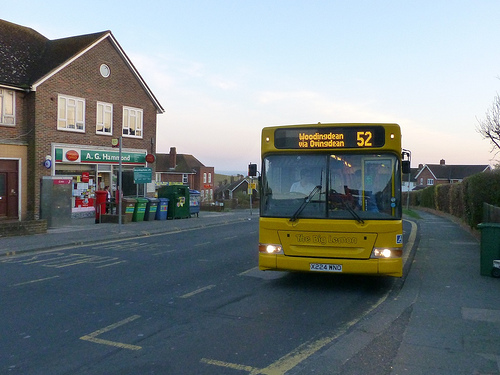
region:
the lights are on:
[255, 245, 424, 266]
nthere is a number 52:
[286, 128, 374, 150]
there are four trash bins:
[119, 199, 174, 218]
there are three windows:
[52, 96, 151, 137]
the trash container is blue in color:
[161, 180, 193, 216]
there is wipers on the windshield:
[280, 190, 360, 225]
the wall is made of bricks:
[67, 87, 150, 101]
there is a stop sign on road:
[37, 245, 116, 288]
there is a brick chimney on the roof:
[165, 142, 181, 170]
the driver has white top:
[283, 175, 324, 203]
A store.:
[31, 35, 169, 243]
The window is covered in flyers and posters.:
[55, 160, 102, 210]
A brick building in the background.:
[152, 145, 212, 211]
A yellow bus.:
[250, 110, 415, 285]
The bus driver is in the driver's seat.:
[276, 165, 321, 210]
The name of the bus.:
[280, 230, 375, 251]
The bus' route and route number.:
[280, 125, 380, 155]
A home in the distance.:
[410, 156, 490, 201]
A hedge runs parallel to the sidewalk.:
[415, 156, 495, 241]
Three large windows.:
[52, 86, 148, 138]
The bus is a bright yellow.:
[240, 126, 446, 312]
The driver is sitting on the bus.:
[283, 167, 320, 209]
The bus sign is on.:
[290, 124, 393, 148]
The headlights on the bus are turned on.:
[264, 231, 445, 261]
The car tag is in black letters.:
[308, 257, 347, 277]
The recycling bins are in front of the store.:
[116, 194, 181, 225]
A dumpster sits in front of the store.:
[160, 180, 206, 227]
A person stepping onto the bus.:
[346, 168, 406, 232]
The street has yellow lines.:
[79, 307, 286, 374]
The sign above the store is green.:
[47, 143, 161, 170]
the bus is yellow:
[246, 113, 416, 325]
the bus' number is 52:
[294, 125, 376, 147]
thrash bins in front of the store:
[119, 188, 174, 223]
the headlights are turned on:
[254, 231, 409, 275]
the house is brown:
[41, 55, 168, 155]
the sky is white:
[201, 56, 285, 100]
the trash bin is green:
[460, 213, 497, 273]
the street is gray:
[105, 276, 220, 361]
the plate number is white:
[302, 255, 340, 279]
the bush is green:
[466, 175, 492, 217]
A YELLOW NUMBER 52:
[348, 123, 378, 153]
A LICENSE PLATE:
[306, 256, 350, 278]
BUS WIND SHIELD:
[254, 146, 411, 226]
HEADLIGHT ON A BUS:
[249, 236, 289, 262]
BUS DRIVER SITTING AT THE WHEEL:
[286, 164, 330, 206]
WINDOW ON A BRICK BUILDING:
[50, 91, 91, 136]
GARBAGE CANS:
[119, 191, 176, 226]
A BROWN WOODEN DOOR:
[3, 152, 23, 227]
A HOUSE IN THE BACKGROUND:
[410, 160, 495, 210]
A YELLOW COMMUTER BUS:
[254, 111, 412, 290]